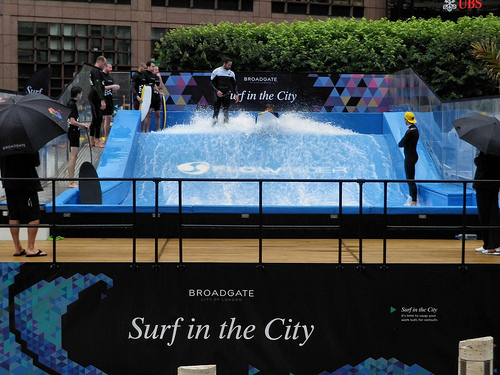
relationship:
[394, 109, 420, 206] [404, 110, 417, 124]
person wearing cap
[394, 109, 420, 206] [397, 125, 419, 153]
person wearing top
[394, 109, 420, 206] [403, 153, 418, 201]
person wearing pants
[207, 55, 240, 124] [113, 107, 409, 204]
man standing in water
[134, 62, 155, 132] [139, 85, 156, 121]
person holding object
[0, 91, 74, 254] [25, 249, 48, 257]
person wearing sandal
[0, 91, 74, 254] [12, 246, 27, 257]
person wearing sandal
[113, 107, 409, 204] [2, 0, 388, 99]
water in front of building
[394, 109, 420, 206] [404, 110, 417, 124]
person in cap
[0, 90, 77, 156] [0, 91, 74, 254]
umbrella over person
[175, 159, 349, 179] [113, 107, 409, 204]
logo under water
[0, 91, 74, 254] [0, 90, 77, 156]
person holding umbrella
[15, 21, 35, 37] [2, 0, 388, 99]
window on building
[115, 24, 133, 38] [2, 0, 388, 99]
window on building